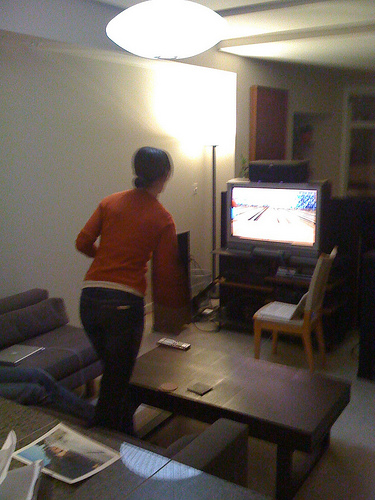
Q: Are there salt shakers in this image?
A: No, there are no salt shakers.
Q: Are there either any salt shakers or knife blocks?
A: No, there are no salt shakers or knife blocks.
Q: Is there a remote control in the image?
A: Yes, there is a remote control.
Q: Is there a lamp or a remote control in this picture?
A: Yes, there is a remote control.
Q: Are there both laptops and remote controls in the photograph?
A: Yes, there are both a remote control and a laptop.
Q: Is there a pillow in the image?
A: No, there are no pillows.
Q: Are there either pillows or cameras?
A: No, there are no pillows or cameras.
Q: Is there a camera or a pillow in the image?
A: No, there are no pillows or cameras.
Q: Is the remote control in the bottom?
A: Yes, the remote control is in the bottom of the image.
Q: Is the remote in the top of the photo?
A: No, the remote is in the bottom of the image.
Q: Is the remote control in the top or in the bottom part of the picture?
A: The remote control is in the bottom of the image.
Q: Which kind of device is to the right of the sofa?
A: The device is a remote control.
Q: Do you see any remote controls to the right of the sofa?
A: Yes, there is a remote control to the right of the sofa.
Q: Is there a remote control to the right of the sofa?
A: Yes, there is a remote control to the right of the sofa.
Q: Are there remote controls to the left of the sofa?
A: No, the remote control is to the right of the sofa.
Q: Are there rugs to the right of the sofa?
A: No, there is a remote control to the right of the sofa.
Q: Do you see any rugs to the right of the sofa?
A: No, there is a remote control to the right of the sofa.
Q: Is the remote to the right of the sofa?
A: Yes, the remote is to the right of the sofa.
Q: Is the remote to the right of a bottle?
A: No, the remote is to the right of the sofa.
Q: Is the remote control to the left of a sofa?
A: No, the remote control is to the right of a sofa.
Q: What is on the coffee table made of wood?
A: The remote control is on the coffee table.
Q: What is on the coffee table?
A: The remote control is on the coffee table.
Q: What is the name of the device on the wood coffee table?
A: The device is a remote control.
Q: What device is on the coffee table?
A: The device is a remote control.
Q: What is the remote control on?
A: The remote control is on the coffee table.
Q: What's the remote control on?
A: The remote control is on the coffee table.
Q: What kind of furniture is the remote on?
A: The remote is on the coffee table.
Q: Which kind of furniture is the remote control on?
A: The remote is on the coffee table.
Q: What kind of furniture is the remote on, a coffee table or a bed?
A: The remote is on a coffee table.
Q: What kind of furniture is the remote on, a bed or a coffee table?
A: The remote is on a coffee table.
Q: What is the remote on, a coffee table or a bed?
A: The remote is on a coffee table.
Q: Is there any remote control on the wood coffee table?
A: Yes, there is a remote control on the coffee table.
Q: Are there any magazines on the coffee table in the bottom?
A: No, there is a remote control on the coffee table.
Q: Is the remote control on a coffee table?
A: Yes, the remote control is on a coffee table.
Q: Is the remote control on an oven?
A: No, the remote control is on a coffee table.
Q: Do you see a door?
A: Yes, there is a door.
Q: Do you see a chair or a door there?
A: Yes, there is a door.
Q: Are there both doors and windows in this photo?
A: No, there is a door but no windows.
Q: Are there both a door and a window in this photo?
A: No, there is a door but no windows.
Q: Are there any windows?
A: No, there are no windows.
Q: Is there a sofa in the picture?
A: Yes, there is a sofa.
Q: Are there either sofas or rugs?
A: Yes, there is a sofa.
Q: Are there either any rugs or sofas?
A: Yes, there is a sofa.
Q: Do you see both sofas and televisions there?
A: Yes, there are both a sofa and a television.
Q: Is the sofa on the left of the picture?
A: Yes, the sofa is on the left of the image.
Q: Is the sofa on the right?
A: No, the sofa is on the left of the image.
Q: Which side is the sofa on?
A: The sofa is on the left of the image.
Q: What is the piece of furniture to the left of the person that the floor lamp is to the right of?
A: The piece of furniture is a sofa.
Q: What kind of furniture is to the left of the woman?
A: The piece of furniture is a sofa.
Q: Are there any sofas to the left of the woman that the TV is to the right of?
A: Yes, there is a sofa to the left of the woman.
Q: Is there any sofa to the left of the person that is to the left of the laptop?
A: Yes, there is a sofa to the left of the woman.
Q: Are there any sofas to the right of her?
A: No, the sofa is to the left of the woman.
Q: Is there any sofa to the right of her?
A: No, the sofa is to the left of the woman.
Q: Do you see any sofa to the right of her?
A: No, the sofa is to the left of the woman.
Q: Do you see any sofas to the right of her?
A: No, the sofa is to the left of the woman.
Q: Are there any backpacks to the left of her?
A: No, there is a sofa to the left of the woman.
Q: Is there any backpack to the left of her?
A: No, there is a sofa to the left of the woman.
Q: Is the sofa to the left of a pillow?
A: No, the sofa is to the left of the woman.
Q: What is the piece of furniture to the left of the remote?
A: The piece of furniture is a sofa.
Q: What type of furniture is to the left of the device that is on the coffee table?
A: The piece of furniture is a sofa.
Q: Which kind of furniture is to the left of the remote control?
A: The piece of furniture is a sofa.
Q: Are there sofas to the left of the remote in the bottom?
A: Yes, there is a sofa to the left of the remote control.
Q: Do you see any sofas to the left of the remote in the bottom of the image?
A: Yes, there is a sofa to the left of the remote control.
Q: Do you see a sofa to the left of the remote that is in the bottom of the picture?
A: Yes, there is a sofa to the left of the remote control.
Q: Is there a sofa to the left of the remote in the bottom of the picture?
A: Yes, there is a sofa to the left of the remote control.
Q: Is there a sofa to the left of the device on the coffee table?
A: Yes, there is a sofa to the left of the remote control.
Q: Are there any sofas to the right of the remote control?
A: No, the sofa is to the left of the remote control.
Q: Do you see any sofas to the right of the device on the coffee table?
A: No, the sofa is to the left of the remote control.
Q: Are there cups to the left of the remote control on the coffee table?
A: No, there is a sofa to the left of the remote control.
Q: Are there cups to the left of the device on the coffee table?
A: No, there is a sofa to the left of the remote control.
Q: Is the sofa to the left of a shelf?
A: No, the sofa is to the left of a remote control.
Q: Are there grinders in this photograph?
A: No, there are no grinders.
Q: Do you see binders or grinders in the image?
A: No, there are no grinders or binders.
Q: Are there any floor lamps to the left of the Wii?
A: Yes, there is a floor lamp to the left of the Wii.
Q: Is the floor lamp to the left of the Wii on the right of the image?
A: Yes, the floor lamp is to the left of the Wii.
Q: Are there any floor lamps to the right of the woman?
A: Yes, there is a floor lamp to the right of the woman.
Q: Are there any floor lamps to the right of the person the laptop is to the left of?
A: Yes, there is a floor lamp to the right of the woman.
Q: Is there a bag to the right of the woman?
A: No, there is a floor lamp to the right of the woman.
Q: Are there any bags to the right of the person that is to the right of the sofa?
A: No, there is a floor lamp to the right of the woman.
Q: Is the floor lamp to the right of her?
A: Yes, the floor lamp is to the right of the woman.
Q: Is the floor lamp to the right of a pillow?
A: No, the floor lamp is to the right of the woman.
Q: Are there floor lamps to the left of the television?
A: Yes, there is a floor lamp to the left of the television.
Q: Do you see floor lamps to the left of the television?
A: Yes, there is a floor lamp to the left of the television.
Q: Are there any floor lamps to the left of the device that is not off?
A: Yes, there is a floor lamp to the left of the television.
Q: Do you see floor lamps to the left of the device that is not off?
A: Yes, there is a floor lamp to the left of the television.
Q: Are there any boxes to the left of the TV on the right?
A: No, there is a floor lamp to the left of the television.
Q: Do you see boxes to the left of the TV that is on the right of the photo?
A: No, there is a floor lamp to the left of the television.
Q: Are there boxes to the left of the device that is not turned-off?
A: No, there is a floor lamp to the left of the television.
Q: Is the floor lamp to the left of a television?
A: Yes, the floor lamp is to the left of a television.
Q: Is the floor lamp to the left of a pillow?
A: No, the floor lamp is to the left of a television.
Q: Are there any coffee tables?
A: Yes, there is a coffee table.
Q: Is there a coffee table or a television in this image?
A: Yes, there is a coffee table.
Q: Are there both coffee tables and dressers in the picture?
A: No, there is a coffee table but no dressers.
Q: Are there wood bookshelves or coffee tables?
A: Yes, there is a wood coffee table.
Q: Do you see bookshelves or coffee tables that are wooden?
A: Yes, the coffee table is wooden.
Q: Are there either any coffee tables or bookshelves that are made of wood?
A: Yes, the coffee table is made of wood.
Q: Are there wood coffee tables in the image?
A: Yes, there is a wood coffee table.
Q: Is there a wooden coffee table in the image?
A: Yes, there is a wood coffee table.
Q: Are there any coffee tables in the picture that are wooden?
A: Yes, there is a coffee table that is wooden.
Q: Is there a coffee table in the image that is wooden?
A: Yes, there is a coffee table that is wooden.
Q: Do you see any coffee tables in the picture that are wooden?
A: Yes, there is a coffee table that is wooden.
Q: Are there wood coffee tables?
A: Yes, there is a coffee table that is made of wood.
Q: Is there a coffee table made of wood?
A: Yes, there is a coffee table that is made of wood.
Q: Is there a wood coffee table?
A: Yes, there is a coffee table that is made of wood.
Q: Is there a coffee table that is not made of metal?
A: Yes, there is a coffee table that is made of wood.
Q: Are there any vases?
A: No, there are no vases.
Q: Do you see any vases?
A: No, there are no vases.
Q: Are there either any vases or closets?
A: No, there are no vases or closets.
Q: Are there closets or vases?
A: No, there are no vases or closets.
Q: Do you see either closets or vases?
A: No, there are no vases or closets.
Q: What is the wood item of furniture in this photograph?
A: The piece of furniture is a coffee table.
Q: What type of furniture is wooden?
A: The furniture is a coffee table.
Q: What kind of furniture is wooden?
A: The furniture is a coffee table.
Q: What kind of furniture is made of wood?
A: The furniture is a coffee table.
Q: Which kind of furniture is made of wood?
A: The furniture is a coffee table.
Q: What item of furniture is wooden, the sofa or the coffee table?
A: The coffee table is wooden.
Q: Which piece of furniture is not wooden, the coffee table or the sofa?
A: The sofa is not wooden.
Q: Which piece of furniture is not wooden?
A: The piece of furniture is a sofa.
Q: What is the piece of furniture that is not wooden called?
A: The piece of furniture is a sofa.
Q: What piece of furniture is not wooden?
A: The piece of furniture is a sofa.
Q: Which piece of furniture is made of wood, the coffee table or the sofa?
A: The coffee table is made of wood.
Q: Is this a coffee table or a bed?
A: This is a coffee table.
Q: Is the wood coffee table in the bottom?
A: Yes, the coffee table is in the bottom of the image.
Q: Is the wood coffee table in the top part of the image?
A: No, the coffee table is in the bottom of the image.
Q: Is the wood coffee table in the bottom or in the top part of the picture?
A: The coffee table is in the bottom of the image.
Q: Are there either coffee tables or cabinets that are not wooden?
A: No, there is a coffee table but it is wooden.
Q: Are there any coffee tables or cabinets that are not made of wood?
A: No, there is a coffee table but it is made of wood.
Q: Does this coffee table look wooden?
A: Yes, the coffee table is wooden.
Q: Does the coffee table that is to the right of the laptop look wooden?
A: Yes, the coffee table is wooden.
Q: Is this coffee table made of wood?
A: Yes, the coffee table is made of wood.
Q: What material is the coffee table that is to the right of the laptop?
A: The coffee table is made of wood.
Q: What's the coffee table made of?
A: The coffee table is made of wood.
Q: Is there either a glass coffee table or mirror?
A: No, there is a coffee table but it is wooden.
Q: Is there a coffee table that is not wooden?
A: No, there is a coffee table but it is wooden.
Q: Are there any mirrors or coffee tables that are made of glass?
A: No, there is a coffee table but it is made of wood.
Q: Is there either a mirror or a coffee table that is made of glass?
A: No, there is a coffee table but it is made of wood.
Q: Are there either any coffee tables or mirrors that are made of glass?
A: No, there is a coffee table but it is made of wood.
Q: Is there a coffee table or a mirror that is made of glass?
A: No, there is a coffee table but it is made of wood.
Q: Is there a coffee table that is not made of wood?
A: No, there is a coffee table but it is made of wood.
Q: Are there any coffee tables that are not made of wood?
A: No, there is a coffee table but it is made of wood.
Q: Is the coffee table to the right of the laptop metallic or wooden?
A: The coffee table is wooden.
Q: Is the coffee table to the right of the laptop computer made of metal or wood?
A: The coffee table is made of wood.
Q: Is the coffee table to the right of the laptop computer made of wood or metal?
A: The coffee table is made of wood.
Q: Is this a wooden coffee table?
A: Yes, this is a wooden coffee table.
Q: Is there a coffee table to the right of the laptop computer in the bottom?
A: Yes, there is a coffee table to the right of the laptop.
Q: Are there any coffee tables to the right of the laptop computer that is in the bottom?
A: Yes, there is a coffee table to the right of the laptop.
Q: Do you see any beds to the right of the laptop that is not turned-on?
A: No, there is a coffee table to the right of the laptop.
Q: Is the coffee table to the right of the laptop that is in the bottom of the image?
A: Yes, the coffee table is to the right of the laptop computer.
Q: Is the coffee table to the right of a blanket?
A: No, the coffee table is to the right of the laptop computer.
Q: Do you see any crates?
A: No, there are no crates.